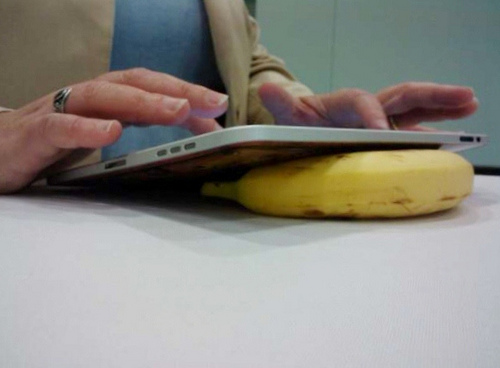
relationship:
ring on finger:
[52, 86, 71, 113] [49, 81, 193, 128]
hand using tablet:
[0, 64, 231, 196] [45, 119, 489, 196]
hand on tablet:
[254, 78, 479, 132] [45, 119, 489, 196]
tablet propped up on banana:
[45, 119, 489, 196] [195, 146, 475, 220]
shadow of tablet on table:
[79, 185, 484, 266] [1, 169, 500, 367]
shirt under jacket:
[95, 0, 262, 160] [0, 1, 316, 177]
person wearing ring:
[0, 0, 481, 207] [52, 86, 71, 113]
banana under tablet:
[195, 146, 475, 220] [45, 119, 489, 196]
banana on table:
[195, 146, 475, 220] [1, 169, 500, 367]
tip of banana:
[198, 176, 223, 200] [195, 146, 475, 220]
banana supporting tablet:
[195, 146, 475, 220] [45, 119, 489, 196]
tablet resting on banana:
[45, 119, 489, 196] [195, 146, 475, 220]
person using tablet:
[0, 0, 481, 207] [45, 119, 489, 196]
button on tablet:
[155, 147, 168, 160] [45, 119, 489, 196]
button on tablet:
[168, 144, 182, 155] [45, 119, 489, 196]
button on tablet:
[182, 141, 197, 150] [45, 119, 489, 196]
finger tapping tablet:
[333, 81, 390, 129] [45, 119, 489, 196]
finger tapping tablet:
[133, 109, 225, 137] [45, 119, 489, 196]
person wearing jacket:
[0, 0, 481, 207] [0, 1, 316, 177]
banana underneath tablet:
[195, 146, 475, 220] [45, 119, 489, 196]